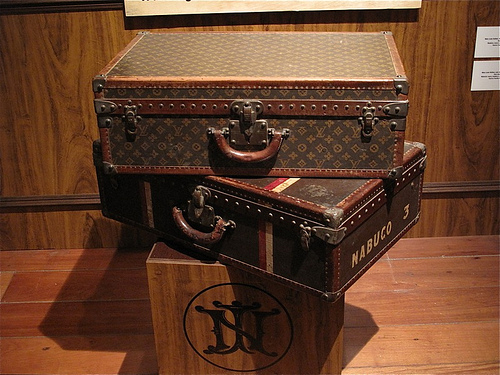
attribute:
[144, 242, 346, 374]
box — wood 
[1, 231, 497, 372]
wood flooring — plank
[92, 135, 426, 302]
luggage — brown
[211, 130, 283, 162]
handle — leather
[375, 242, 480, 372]
wood floor — surface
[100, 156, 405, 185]
trim — brown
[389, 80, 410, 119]
frames — metal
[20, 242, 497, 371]
floor — brown, wood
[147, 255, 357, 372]
square box — tall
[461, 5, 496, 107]
cards — white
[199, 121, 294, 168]
handle — leather 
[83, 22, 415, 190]
luggage — old 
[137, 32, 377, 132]
suitcase — top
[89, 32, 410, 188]
antique suitcase — stacked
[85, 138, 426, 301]
antique suitcase — stacked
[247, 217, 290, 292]
bands — white, red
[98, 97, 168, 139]
latch — metal 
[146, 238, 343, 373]
block — wood 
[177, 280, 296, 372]
engraving — black 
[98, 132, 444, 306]
luggage — pieces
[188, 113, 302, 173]
handle — brown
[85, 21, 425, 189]
suitcase — little, brown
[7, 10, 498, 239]
wall — brown, wooden, wood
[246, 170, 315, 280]
stripes — red, white